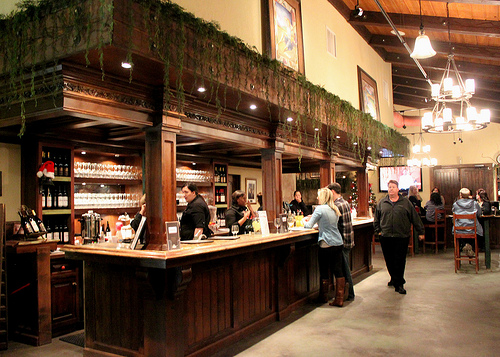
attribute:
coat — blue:
[451, 197, 485, 236]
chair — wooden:
[451, 210, 478, 272]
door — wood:
[427, 162, 494, 202]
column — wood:
[143, 126, 213, 211]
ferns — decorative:
[1, 5, 411, 161]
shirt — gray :
[375, 197, 421, 239]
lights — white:
[404, 27, 493, 137]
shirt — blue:
[301, 203, 346, 245]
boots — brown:
[327, 271, 348, 310]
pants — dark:
[367, 197, 440, 302]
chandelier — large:
[420, 60, 491, 136]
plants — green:
[188, 45, 410, 177]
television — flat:
[378, 162, 423, 192]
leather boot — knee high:
[332, 280, 348, 308]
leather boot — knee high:
[319, 278, 329, 303]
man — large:
[335, 160, 431, 296]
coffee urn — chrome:
[81, 208, 104, 247]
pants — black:
[379, 232, 416, 289]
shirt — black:
[176, 200, 210, 240]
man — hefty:
[377, 178, 427, 295]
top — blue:
[451, 193, 486, 239]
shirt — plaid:
[332, 193, 356, 244]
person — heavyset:
[178, 183, 214, 237]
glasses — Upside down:
[78, 160, 142, 203]